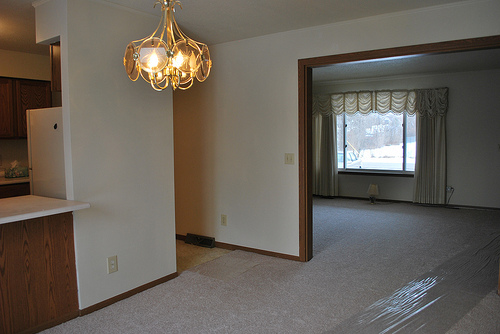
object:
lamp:
[367, 183, 379, 204]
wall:
[96, 173, 156, 243]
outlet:
[106, 255, 118, 275]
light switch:
[285, 153, 295, 165]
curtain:
[312, 92, 339, 197]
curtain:
[413, 88, 449, 204]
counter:
[0, 194, 91, 225]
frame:
[0, 195, 90, 334]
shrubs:
[343, 142, 365, 162]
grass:
[364, 141, 414, 168]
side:
[26, 107, 66, 200]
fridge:
[26, 107, 68, 200]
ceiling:
[203, 0, 379, 31]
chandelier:
[123, 0, 213, 93]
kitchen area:
[1, 1, 64, 196]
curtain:
[312, 88, 450, 205]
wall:
[460, 98, 498, 209]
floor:
[155, 286, 493, 331]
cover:
[324, 232, 500, 333]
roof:
[103, 2, 427, 47]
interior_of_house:
[1, 1, 500, 334]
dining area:
[0, 0, 498, 330]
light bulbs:
[172, 51, 184, 68]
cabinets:
[0, 76, 53, 139]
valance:
[312, 88, 449, 119]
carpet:
[36, 198, 500, 334]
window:
[331, 92, 417, 172]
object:
[185, 233, 216, 248]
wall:
[215, 78, 278, 199]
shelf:
[338, 168, 415, 178]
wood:
[11, 232, 64, 309]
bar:
[0, 194, 91, 334]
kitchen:
[0, 1, 67, 220]